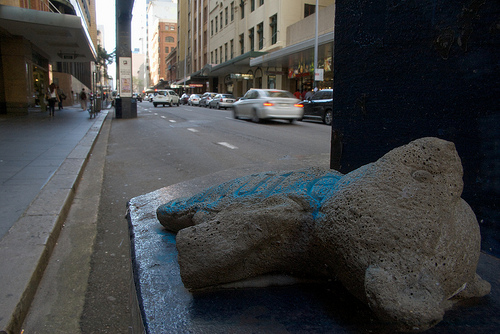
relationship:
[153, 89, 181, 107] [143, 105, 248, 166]
car turning down street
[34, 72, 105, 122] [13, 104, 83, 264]
people are walking sidewalk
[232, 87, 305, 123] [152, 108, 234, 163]
car in street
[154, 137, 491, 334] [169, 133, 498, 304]
bear in shape of bear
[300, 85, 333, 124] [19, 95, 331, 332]
car on road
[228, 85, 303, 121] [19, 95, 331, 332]
car on road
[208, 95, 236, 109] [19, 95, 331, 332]
car on road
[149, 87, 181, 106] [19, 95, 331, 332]
car on road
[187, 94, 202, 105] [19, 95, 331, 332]
car on road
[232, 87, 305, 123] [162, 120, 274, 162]
car on street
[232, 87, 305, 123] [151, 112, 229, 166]
car driving on street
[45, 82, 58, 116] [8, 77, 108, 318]
person walking sidewalk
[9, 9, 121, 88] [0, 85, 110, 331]
overhang over sidewalk